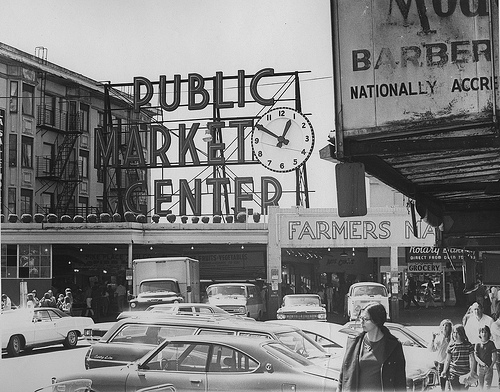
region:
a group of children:
[431, 311, 497, 381]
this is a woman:
[325, 290, 412, 390]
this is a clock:
[232, 91, 333, 176]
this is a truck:
[112, 239, 205, 325]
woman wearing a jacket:
[319, 310, 404, 385]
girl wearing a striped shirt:
[442, 334, 474, 376]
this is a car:
[40, 336, 347, 389]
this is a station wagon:
[75, 290, 395, 377]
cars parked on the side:
[48, 272, 430, 389]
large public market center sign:
[56, 53, 310, 230]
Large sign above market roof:
[91, 67, 318, 221]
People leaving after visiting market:
[336, 299, 499, 390]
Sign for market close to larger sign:
[286, 218, 434, 241]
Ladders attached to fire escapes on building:
[38, 112, 81, 216]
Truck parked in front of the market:
[128, 255, 201, 310]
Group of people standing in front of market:
[2, 287, 74, 315]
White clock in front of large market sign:
[250, 106, 315, 173]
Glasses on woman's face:
[356, 314, 371, 322]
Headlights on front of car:
[278, 311, 325, 319]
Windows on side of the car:
[137, 338, 262, 374]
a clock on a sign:
[239, 86, 349, 181]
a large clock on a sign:
[232, 83, 336, 217]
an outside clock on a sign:
[200, 56, 370, 209]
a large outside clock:
[228, 93, 374, 214]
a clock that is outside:
[239, 99, 346, 201]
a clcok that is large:
[255, 100, 311, 187]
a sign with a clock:
[205, 61, 406, 277]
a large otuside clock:
[222, 93, 396, 254]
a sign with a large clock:
[227, 54, 393, 277]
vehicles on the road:
[132, 254, 303, 389]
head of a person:
[360, 293, 410, 329]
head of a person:
[431, 310, 450, 333]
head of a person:
[447, 323, 468, 335]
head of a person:
[476, 323, 491, 344]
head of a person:
[462, 302, 498, 327]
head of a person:
[61, 286, 74, 305]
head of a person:
[42, 293, 56, 304]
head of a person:
[25, 287, 36, 299]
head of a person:
[109, 272, 121, 284]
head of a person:
[324, 278, 337, 289]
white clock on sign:
[240, 110, 325, 188]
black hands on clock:
[251, 106, 321, 173]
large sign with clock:
[101, 75, 298, 256]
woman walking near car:
[319, 282, 420, 390]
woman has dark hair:
[360, 290, 387, 320]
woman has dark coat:
[344, 326, 431, 390]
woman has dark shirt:
[363, 338, 385, 388]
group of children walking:
[412, 278, 494, 373]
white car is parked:
[6, 301, 86, 348]